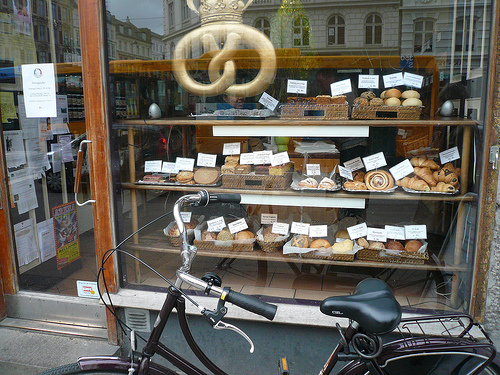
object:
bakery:
[0, 0, 500, 340]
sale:
[102, 68, 467, 266]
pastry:
[308, 236, 332, 250]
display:
[225, 216, 251, 236]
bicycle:
[34, 189, 500, 375]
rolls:
[364, 166, 395, 195]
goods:
[173, 169, 195, 183]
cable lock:
[334, 321, 386, 360]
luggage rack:
[354, 314, 493, 360]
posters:
[0, 127, 31, 178]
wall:
[0, 0, 89, 275]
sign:
[18, 59, 60, 119]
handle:
[72, 137, 99, 207]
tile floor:
[23, 196, 465, 314]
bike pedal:
[275, 353, 292, 375]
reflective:
[179, 188, 477, 315]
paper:
[20, 60, 59, 120]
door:
[0, 0, 108, 333]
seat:
[317, 276, 404, 332]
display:
[381, 224, 405, 241]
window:
[101, 0, 496, 318]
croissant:
[410, 176, 429, 192]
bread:
[193, 165, 220, 186]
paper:
[358, 149, 390, 173]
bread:
[383, 86, 403, 99]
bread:
[314, 176, 340, 189]